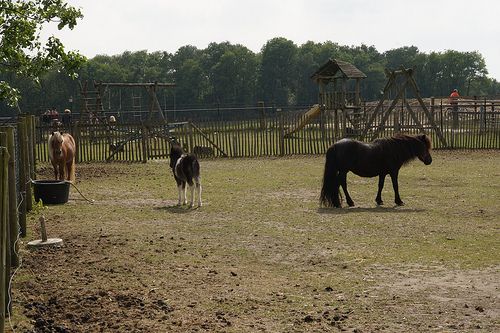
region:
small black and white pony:
[166, 133, 204, 211]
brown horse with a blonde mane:
[46, 125, 78, 183]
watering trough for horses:
[29, 175, 74, 207]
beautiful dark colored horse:
[314, 121, 434, 210]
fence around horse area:
[33, 110, 498, 165]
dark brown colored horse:
[317, 129, 435, 204]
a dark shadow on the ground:
[315, 202, 425, 217]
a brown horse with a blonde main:
[46, 128, 77, 181]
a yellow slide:
[281, 101, 319, 142]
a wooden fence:
[0, 95, 499, 316]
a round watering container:
[32, 178, 71, 205]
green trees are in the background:
[14, 36, 497, 119]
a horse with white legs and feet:
[167, 138, 203, 206]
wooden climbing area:
[75, 78, 177, 127]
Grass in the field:
[249, 182, 297, 242]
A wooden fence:
[179, 117, 279, 157]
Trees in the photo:
[197, 43, 309, 93]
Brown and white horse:
[43, 130, 86, 175]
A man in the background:
[438, 84, 468, 127]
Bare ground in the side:
[109, 237, 203, 310]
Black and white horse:
[160, 138, 212, 209]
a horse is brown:
[298, 119, 460, 209]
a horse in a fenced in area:
[162, 129, 207, 219]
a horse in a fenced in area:
[44, 126, 81, 193]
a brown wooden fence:
[204, 100, 392, 186]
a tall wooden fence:
[222, 109, 359, 166]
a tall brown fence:
[232, 115, 349, 170]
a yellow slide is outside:
[282, 84, 343, 146]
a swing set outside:
[73, 59, 214, 147]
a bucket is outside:
[26, 165, 141, 260]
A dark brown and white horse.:
[166, 142, 201, 208]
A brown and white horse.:
[45, 127, 75, 182]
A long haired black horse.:
[316, 132, 428, 207]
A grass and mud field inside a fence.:
[15, 160, 496, 330]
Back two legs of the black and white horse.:
[185, 174, 203, 209]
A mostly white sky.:
[3, 2, 498, 72]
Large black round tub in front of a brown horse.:
[29, 176, 69, 205]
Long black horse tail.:
[317, 146, 342, 209]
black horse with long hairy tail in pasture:
[310, 120, 434, 217]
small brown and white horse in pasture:
[162, 138, 209, 226]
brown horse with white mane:
[46, 124, 91, 201]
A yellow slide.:
[281, 100, 321, 137]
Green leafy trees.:
[2, 1, 492, 114]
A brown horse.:
[40, 120, 94, 190]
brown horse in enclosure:
[47, 129, 75, 170]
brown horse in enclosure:
[165, 134, 205, 206]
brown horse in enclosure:
[312, 121, 440, 222]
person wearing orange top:
[446, 79, 477, 126]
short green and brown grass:
[308, 257, 345, 280]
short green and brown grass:
[441, 256, 466, 293]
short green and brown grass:
[257, 174, 305, 231]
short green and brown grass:
[111, 205, 175, 270]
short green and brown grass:
[101, 296, 157, 330]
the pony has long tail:
[309, 126, 439, 220]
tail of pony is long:
[313, 141, 347, 211]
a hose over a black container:
[28, 173, 75, 209]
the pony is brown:
[41, 126, 83, 183]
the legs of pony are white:
[161, 128, 210, 218]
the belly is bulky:
[348, 156, 384, 181]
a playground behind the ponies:
[275, 47, 370, 144]